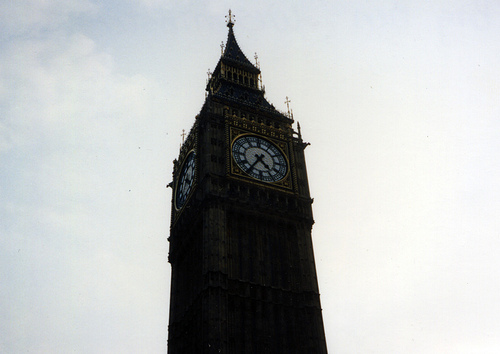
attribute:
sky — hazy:
[370, 103, 450, 246]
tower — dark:
[165, 11, 335, 347]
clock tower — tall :
[159, 2, 341, 352]